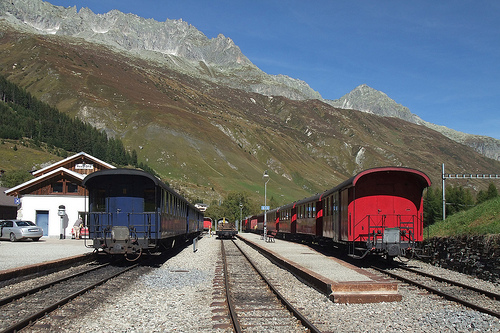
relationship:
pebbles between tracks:
[99, 252, 209, 331] [211, 207, 296, 328]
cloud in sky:
[248, 50, 342, 83] [47, 2, 498, 143]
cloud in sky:
[54, 0, 500, 136] [47, 2, 498, 143]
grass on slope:
[425, 190, 499, 230] [404, 187, 499, 257]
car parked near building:
[0, 218, 44, 242] [3, 164, 85, 234]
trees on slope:
[0, 115, 124, 160] [0, 128, 73, 163]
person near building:
[69, 210, 81, 235] [16, 146, 94, 244]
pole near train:
[262, 175, 270, 243] [247, 164, 428, 276]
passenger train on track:
[239, 165, 435, 263] [381, 255, 498, 317]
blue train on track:
[78, 165, 206, 265] [11, 258, 131, 331]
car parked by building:
[0, 218, 44, 242] [12, 145, 114, 246]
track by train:
[211, 237, 321, 331] [78, 167, 205, 261]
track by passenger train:
[211, 237, 321, 331] [239, 165, 435, 263]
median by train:
[235, 232, 402, 303] [78, 167, 205, 261]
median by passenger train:
[235, 232, 402, 303] [239, 165, 435, 263]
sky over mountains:
[47, 2, 498, 143] [2, 0, 497, 231]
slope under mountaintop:
[4, 27, 497, 230] [326, 80, 416, 115]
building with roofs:
[8, 149, 121, 241] [6, 152, 118, 194]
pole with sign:
[252, 164, 273, 245] [252, 201, 274, 212]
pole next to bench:
[252, 164, 273, 245] [260, 227, 279, 243]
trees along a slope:
[0, 74, 173, 187] [5, 66, 180, 196]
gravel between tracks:
[150, 277, 221, 318] [2, 260, 132, 330]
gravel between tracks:
[150, 277, 221, 318] [215, 233, 315, 330]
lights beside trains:
[438, 161, 499, 229] [243, 162, 427, 267]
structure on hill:
[435, 160, 497, 214] [443, 188, 493, 228]